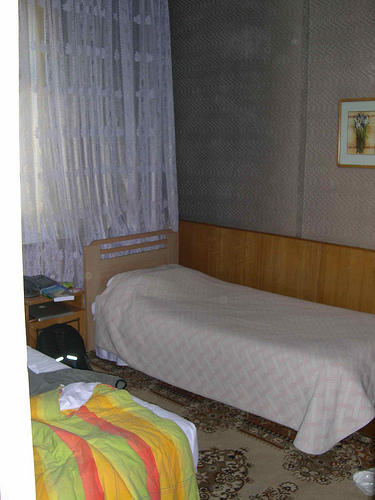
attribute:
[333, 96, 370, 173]
portrait — framed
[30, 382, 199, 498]
bedspread — colorful, striped, green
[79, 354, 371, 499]
carpet — oriental, neutral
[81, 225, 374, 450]
bed — twin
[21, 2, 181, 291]
curtain — white, lace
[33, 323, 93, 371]
bag — black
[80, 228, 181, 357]
headboard — wooden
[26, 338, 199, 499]
bed — twin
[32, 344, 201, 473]
sheet — white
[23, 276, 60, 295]
phone — black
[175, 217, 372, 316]
paneling — wooden, brown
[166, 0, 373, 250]
wallpaper — gray